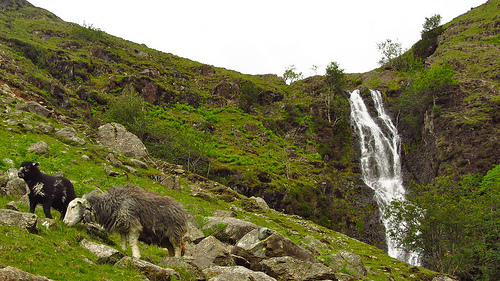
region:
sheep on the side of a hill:
[60, 181, 200, 263]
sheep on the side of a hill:
[15, 158, 77, 223]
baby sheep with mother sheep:
[17, 154, 193, 263]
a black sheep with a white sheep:
[15, 156, 195, 261]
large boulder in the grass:
[93, 121, 158, 168]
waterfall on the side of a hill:
[336, 71, 437, 265]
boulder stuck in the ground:
[27, 138, 48, 155]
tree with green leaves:
[317, 58, 348, 115]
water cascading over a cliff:
[342, 76, 432, 271]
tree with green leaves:
[378, 169, 498, 278]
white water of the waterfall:
[335, 81, 438, 258]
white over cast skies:
[187, 1, 349, 54]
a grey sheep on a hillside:
[65, 186, 195, 263]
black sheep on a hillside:
[11, 152, 74, 214]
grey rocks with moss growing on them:
[181, 205, 327, 277]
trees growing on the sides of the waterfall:
[325, 51, 455, 150]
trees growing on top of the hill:
[368, 6, 460, 64]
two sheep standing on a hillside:
[3, 133, 223, 270]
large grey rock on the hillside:
[84, 111, 151, 158]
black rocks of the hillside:
[28, 41, 121, 123]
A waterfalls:
[336, 53, 399, 243]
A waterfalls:
[346, 101, 407, 275]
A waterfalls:
[342, 79, 377, 276]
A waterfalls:
[318, 108, 388, 278]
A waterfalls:
[391, 69, 443, 276]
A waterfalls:
[258, 75, 378, 210]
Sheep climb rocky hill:
[18, 157, 192, 264]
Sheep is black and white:
[17, 158, 74, 223]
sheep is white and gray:
[63, 187, 188, 258]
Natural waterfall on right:
[346, 76, 428, 269]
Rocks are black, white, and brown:
[2, 2, 497, 279]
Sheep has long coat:
[62, 181, 190, 251]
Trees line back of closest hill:
[96, 89, 499, 277]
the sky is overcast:
[31, 0, 488, 85]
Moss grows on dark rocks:
[90, 72, 328, 196]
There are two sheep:
[15, 161, 189, 258]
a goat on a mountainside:
[57, 173, 199, 263]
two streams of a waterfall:
[336, 82, 418, 164]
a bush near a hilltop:
[364, 30, 411, 73]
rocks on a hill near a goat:
[190, 211, 260, 279]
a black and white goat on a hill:
[17, 145, 76, 222]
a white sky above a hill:
[89, 9, 312, 93]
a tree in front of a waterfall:
[367, 188, 440, 255]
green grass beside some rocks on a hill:
[70, 146, 139, 181]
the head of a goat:
[60, 197, 95, 229]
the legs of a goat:
[115, 223, 196, 266]